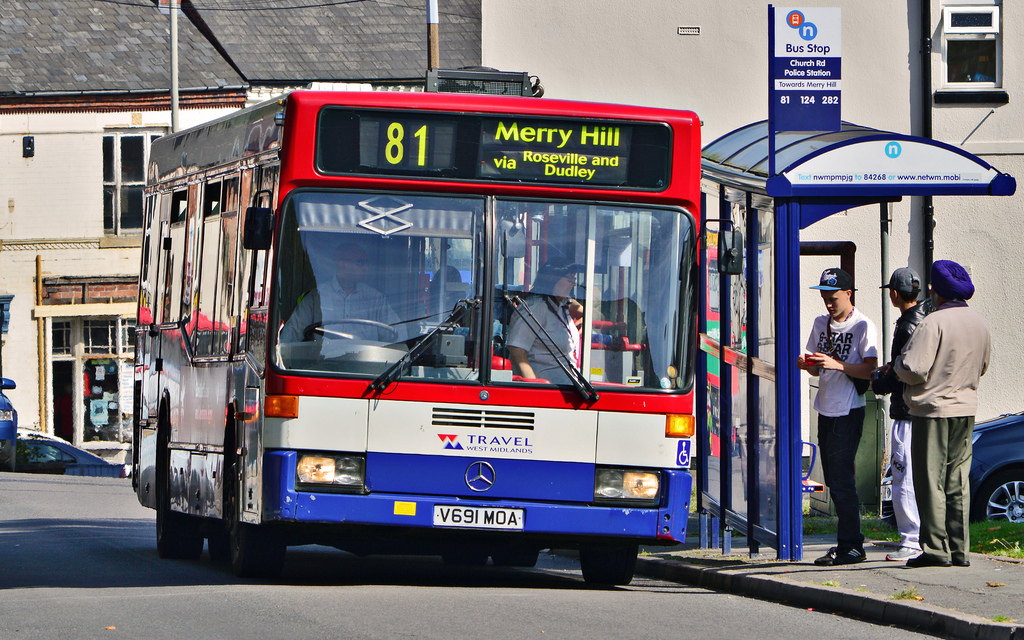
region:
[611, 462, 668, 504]
a headlight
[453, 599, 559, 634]
the ground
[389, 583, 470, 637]
the street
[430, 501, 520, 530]
a license plate on the bus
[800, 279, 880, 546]
a man standing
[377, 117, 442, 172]
a number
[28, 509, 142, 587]
a shadow on the street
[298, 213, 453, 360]
a window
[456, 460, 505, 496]
a sign on the bus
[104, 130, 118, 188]
a window on a building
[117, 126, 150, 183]
a window on a building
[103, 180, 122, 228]
a window on a building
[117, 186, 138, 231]
a window on a building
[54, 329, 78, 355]
a window on a building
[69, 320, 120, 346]
a window on a building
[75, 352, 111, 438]
a window on a building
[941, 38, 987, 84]
a window on a building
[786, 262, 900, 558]
a person walking on a sidewalk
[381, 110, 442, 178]
the yellow numbers 8 and 1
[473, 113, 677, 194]
sign showing the words merry hill via roseville and dudley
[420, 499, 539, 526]
license plate displaying V691 MOA on it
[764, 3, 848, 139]
blue and white bus stop sign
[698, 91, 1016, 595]
three men waiting under a bus stop stand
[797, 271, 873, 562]
a boy looking at a cell phone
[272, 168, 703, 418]
two windows on front of bus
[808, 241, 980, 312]
three heads wearing blue caps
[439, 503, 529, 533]
license plate on the bus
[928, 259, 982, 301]
man wearing a purple turban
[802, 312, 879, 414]
boy wearing a white tee shirt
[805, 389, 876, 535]
boy wearing blue pants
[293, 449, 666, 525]
headlights on the bus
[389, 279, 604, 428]
windshield wipers on the bus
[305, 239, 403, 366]
bus driver operating the bus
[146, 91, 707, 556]
A bus at a bus stop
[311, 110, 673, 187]
A sign on the front of a bus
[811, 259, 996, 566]
People standing at a bus stop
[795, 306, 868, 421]
A white shirt on a man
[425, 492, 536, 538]
A white license plate on a bus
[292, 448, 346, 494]
A headlight on a bus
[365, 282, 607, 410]
Windshield wipers on a bus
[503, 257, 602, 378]
A passenger inside a bus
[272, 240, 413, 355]
A driver inside a bus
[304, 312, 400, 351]
A steering wheel on a bus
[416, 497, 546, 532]
white license plate with black lettering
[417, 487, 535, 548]
white license plate with black lettering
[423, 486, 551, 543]
white license plate with black lettering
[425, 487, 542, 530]
white license plate with black lettering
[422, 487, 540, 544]
white license plate with black lettering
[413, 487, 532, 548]
white license plate with black lettering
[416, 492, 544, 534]
white license plate with black lettering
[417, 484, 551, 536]
white license plate with black lettering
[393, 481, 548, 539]
white license plate with black lettering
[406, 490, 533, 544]
white license plate with black lettering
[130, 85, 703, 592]
a colorful bus near the bus stop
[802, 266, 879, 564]
young man in a white t-shirt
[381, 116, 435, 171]
the number 81 on above the windshield of the bus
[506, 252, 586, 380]
a woman inside the bus near the driver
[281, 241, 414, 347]
the bus driver at the wheel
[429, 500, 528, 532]
the license plate on the bus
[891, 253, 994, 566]
a man wearing a purple turban